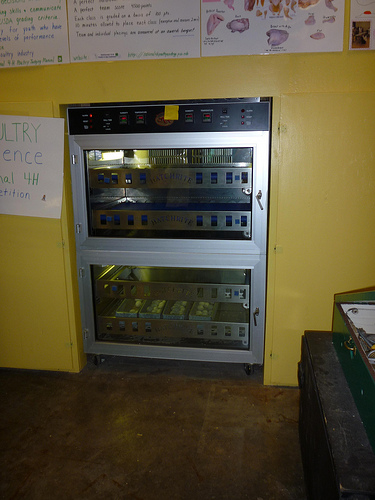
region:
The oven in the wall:
[50, 82, 285, 387]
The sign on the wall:
[1, 112, 67, 222]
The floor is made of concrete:
[44, 402, 265, 496]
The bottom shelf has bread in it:
[106, 299, 247, 345]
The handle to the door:
[253, 189, 266, 220]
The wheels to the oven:
[88, 350, 257, 380]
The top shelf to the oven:
[85, 152, 252, 195]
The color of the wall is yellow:
[301, 82, 369, 262]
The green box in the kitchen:
[326, 283, 373, 434]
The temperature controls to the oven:
[66, 104, 261, 130]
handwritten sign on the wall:
[0, 111, 68, 225]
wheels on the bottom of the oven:
[92, 354, 257, 373]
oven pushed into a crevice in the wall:
[49, 93, 275, 383]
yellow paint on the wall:
[0, 0, 368, 383]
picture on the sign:
[223, 16, 254, 33]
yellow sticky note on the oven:
[161, 104, 184, 120]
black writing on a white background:
[68, 0, 204, 40]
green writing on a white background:
[0, 0, 67, 25]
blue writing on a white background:
[0, 19, 71, 43]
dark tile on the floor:
[1, 370, 312, 498]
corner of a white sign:
[0, 110, 76, 218]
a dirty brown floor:
[1, 360, 312, 498]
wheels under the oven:
[91, 351, 261, 383]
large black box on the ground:
[291, 325, 368, 496]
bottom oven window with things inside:
[80, 248, 272, 366]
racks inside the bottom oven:
[94, 274, 247, 340]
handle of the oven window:
[248, 302, 259, 325]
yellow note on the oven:
[158, 103, 183, 123]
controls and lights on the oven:
[60, 102, 278, 132]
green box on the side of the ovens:
[328, 278, 373, 419]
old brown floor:
[3, 366, 315, 497]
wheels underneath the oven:
[87, 348, 263, 379]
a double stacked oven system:
[63, 101, 277, 375]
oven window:
[87, 261, 260, 352]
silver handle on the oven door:
[250, 307, 260, 328]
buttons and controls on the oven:
[64, 103, 271, 128]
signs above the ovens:
[3, 1, 373, 70]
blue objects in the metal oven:
[78, 154, 256, 242]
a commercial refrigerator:
[60, 101, 266, 377]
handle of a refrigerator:
[255, 186, 267, 212]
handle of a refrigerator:
[250, 307, 261, 325]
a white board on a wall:
[2, 112, 74, 229]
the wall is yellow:
[5, 43, 373, 396]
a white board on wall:
[199, 5, 352, 67]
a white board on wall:
[66, 2, 203, 70]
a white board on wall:
[3, 5, 72, 74]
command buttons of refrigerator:
[63, 100, 269, 139]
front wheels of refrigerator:
[88, 353, 258, 377]